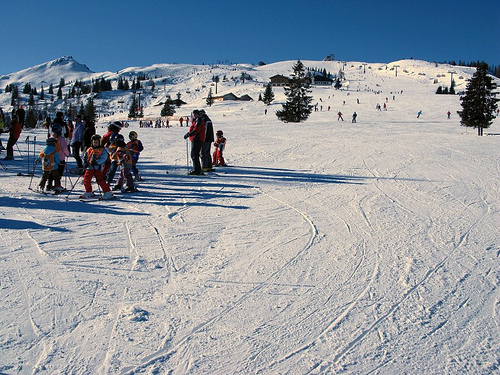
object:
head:
[86, 135, 104, 151]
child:
[79, 134, 111, 199]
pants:
[189, 141, 203, 176]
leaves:
[454, 62, 497, 128]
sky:
[0, 0, 499, 83]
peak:
[46, 54, 83, 67]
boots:
[97, 180, 114, 201]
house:
[266, 73, 289, 89]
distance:
[0, 37, 499, 89]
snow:
[0, 54, 499, 374]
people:
[181, 111, 206, 174]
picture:
[2, 1, 497, 373]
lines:
[103, 221, 140, 363]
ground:
[2, 102, 499, 375]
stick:
[64, 167, 84, 204]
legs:
[96, 168, 112, 205]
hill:
[0, 53, 122, 101]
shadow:
[0, 166, 440, 237]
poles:
[184, 135, 189, 177]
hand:
[181, 130, 195, 140]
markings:
[143, 205, 384, 365]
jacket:
[188, 113, 208, 144]